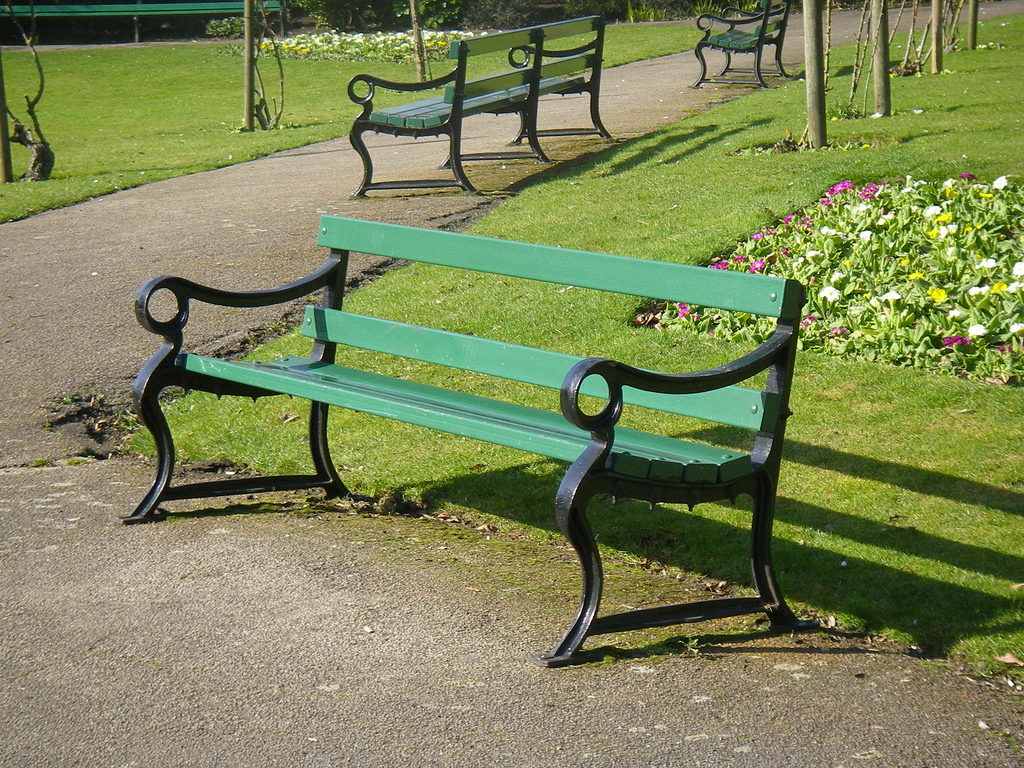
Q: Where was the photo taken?
A: At a park.